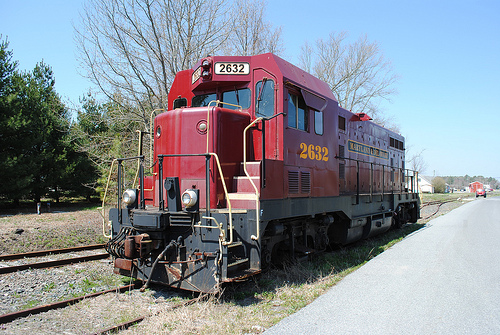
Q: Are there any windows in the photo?
A: Yes, there are windows.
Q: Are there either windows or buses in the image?
A: Yes, there are windows.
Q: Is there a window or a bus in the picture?
A: Yes, there are windows.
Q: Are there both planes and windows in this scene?
A: No, there are windows but no airplanes.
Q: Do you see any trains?
A: Yes, there is a train.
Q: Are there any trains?
A: Yes, there is a train.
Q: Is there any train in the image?
A: Yes, there is a train.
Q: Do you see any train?
A: Yes, there is a train.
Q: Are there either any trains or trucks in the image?
A: Yes, there is a train.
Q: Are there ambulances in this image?
A: No, there are no ambulances.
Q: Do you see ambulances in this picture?
A: No, there are no ambulances.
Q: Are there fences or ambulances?
A: No, there are no ambulances or fences.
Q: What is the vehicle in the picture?
A: The vehicle is a train.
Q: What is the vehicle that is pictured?
A: The vehicle is a train.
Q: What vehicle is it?
A: The vehicle is a train.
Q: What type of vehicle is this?
A: This is a train.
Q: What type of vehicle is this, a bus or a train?
A: This is a train.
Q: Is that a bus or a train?
A: That is a train.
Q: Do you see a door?
A: Yes, there is a door.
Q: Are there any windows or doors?
A: Yes, there is a door.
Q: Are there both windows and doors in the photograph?
A: Yes, there are both a door and a window.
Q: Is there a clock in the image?
A: No, there are no clocks.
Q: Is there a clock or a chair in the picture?
A: No, there are no clocks or chairs.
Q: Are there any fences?
A: No, there are no fences.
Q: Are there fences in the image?
A: No, there are no fences.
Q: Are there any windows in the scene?
A: Yes, there is a window.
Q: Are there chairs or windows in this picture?
A: Yes, there is a window.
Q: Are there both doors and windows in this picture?
A: Yes, there are both a window and a door.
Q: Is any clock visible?
A: No, there are no clocks.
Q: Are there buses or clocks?
A: No, there are no clocks or buses.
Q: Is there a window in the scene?
A: Yes, there is a window.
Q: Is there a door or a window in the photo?
A: Yes, there is a window.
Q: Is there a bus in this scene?
A: No, there are no buses.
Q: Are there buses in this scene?
A: No, there are no buses.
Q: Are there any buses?
A: No, there are no buses.